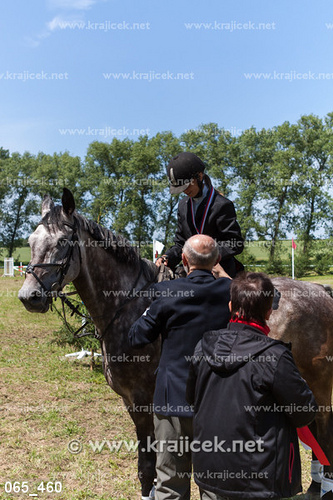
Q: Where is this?
A: This is at the field.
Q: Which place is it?
A: It is a field.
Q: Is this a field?
A: Yes, it is a field.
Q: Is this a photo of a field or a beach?
A: It is showing a field.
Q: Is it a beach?
A: No, it is a field.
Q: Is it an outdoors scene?
A: Yes, it is outdoors.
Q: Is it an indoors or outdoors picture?
A: It is outdoors.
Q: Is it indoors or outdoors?
A: It is outdoors.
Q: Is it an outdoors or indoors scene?
A: It is outdoors.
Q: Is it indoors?
A: No, it is outdoors.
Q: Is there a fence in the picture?
A: No, there are no fences.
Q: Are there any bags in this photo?
A: No, there are no bags.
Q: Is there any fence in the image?
A: No, there are no fences.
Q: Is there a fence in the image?
A: No, there are no fences.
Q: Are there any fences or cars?
A: No, there are no fences or cars.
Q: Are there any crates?
A: No, there are no crates.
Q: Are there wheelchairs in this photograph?
A: No, there are no wheelchairs.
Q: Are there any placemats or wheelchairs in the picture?
A: No, there are no wheelchairs or placemats.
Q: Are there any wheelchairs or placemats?
A: No, there are no wheelchairs or placemats.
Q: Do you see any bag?
A: No, there are no bags.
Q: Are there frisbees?
A: No, there are no frisbees.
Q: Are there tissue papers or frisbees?
A: No, there are no frisbees or tissue papers.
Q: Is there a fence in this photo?
A: No, there are no fences.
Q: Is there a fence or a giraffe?
A: No, there are no fences or giraffes.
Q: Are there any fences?
A: No, there are no fences.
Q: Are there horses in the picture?
A: Yes, there is a horse.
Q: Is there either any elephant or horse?
A: Yes, there is a horse.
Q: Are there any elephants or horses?
A: Yes, there is a horse.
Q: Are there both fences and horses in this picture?
A: No, there is a horse but no fences.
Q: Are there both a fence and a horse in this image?
A: No, there is a horse but no fences.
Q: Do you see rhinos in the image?
A: No, there are no rhinos.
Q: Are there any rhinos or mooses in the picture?
A: No, there are no rhinos or mooses.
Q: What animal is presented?
A: The animal is a horse.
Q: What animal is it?
A: The animal is a horse.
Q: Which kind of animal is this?
A: This is a horse.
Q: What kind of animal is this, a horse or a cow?
A: This is a horse.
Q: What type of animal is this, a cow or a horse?
A: This is a horse.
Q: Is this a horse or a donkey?
A: This is a horse.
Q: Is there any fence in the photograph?
A: No, there are no fences.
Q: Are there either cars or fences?
A: No, there are no fences or cars.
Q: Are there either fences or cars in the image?
A: No, there are no fences or cars.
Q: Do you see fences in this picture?
A: No, there are no fences.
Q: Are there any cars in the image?
A: No, there are no cars.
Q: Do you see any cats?
A: No, there are no cats.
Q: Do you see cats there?
A: No, there are no cats.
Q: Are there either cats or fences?
A: No, there are no cats or fences.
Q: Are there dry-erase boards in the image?
A: No, there are no dry-erase boards.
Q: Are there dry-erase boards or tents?
A: No, there are no dry-erase boards or tents.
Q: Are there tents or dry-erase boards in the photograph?
A: No, there are no dry-erase boards or tents.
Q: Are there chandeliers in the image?
A: No, there are no chandeliers.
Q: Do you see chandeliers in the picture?
A: No, there are no chandeliers.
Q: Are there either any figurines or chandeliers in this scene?
A: No, there are no chandeliers or figurines.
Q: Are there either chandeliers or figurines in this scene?
A: No, there are no chandeliers or figurines.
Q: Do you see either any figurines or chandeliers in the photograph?
A: No, there are no chandeliers or figurines.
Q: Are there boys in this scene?
A: No, there are no boys.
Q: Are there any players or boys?
A: No, there are no boys or players.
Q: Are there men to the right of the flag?
A: No, the man is to the left of the flag.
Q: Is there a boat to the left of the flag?
A: No, there is a man to the left of the flag.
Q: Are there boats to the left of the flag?
A: No, there is a man to the left of the flag.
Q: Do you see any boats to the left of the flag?
A: No, there is a man to the left of the flag.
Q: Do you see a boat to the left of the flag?
A: No, there is a man to the left of the flag.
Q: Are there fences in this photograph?
A: No, there are no fences.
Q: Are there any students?
A: No, there are no students.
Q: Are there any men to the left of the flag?
A: Yes, there is a man to the left of the flag.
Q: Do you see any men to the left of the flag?
A: Yes, there is a man to the left of the flag.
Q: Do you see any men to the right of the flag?
A: No, the man is to the left of the flag.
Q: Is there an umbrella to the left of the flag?
A: No, there is a man to the left of the flag.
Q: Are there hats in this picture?
A: Yes, there is a hat.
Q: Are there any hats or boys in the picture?
A: Yes, there is a hat.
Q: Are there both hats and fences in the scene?
A: No, there is a hat but no fences.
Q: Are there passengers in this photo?
A: No, there are no passengers.